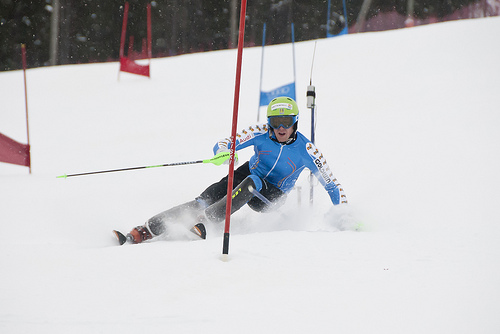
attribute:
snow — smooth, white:
[383, 140, 475, 265]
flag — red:
[0, 42, 39, 174]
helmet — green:
[265, 95, 300, 133]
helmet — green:
[266, 96, 299, 119]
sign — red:
[1, 108, 46, 175]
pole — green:
[202, 138, 253, 170]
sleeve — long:
[305, 136, 352, 228]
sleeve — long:
[211, 123, 258, 165]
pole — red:
[209, 21, 259, 256]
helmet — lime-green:
[262, 98, 314, 136]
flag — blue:
[255, 85, 300, 102]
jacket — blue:
[222, 124, 320, 208]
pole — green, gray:
[217, 3, 250, 267]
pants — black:
[134, 162, 297, 238]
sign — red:
[120, 58, 152, 78]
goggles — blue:
[268, 111, 303, 132]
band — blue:
[242, 175, 264, 204]